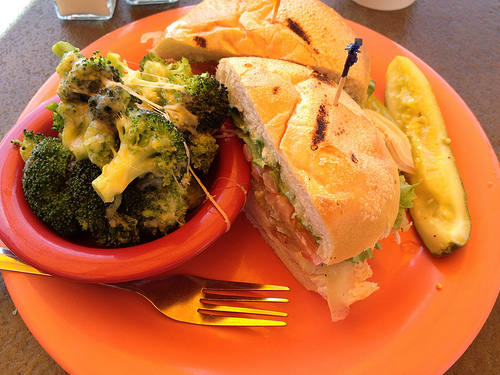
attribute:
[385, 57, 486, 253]
pickle — green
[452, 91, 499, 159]
plate — orange, round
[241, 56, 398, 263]
sandwhich — big, half, cut, sliced, large, round, close, brown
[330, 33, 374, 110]
toothpick — black, brown, standing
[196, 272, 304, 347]
fork — silver, close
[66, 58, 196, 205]
brocolli — green, creamy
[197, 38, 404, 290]
tomato — sliced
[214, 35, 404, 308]
sandwich — half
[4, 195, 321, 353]
fork — metal